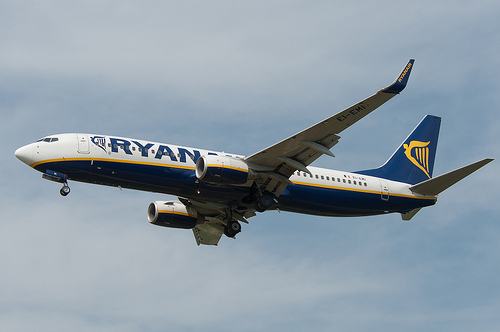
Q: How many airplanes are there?
A: One.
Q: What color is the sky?
A: Blue.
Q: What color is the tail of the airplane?
A: Blue and yellow.